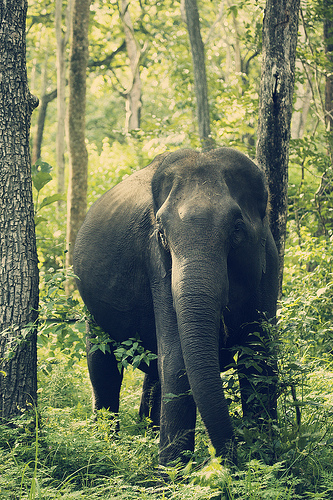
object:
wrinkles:
[177, 260, 216, 295]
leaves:
[46, 300, 56, 318]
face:
[147, 155, 265, 327]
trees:
[0, 0, 333, 423]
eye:
[154, 218, 169, 250]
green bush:
[0, 340, 231, 499]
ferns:
[181, 441, 243, 492]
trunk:
[166, 258, 236, 463]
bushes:
[235, 0, 332, 499]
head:
[150, 146, 269, 471]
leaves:
[41, 258, 56, 288]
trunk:
[1, 0, 40, 425]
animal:
[71, 148, 281, 473]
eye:
[228, 214, 249, 243]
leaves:
[131, 30, 226, 98]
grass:
[0, 223, 333, 500]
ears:
[206, 145, 268, 303]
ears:
[151, 147, 195, 279]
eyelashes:
[151, 224, 165, 233]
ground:
[0, 131, 333, 499]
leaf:
[74, 319, 87, 334]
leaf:
[84, 344, 98, 355]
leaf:
[98, 342, 107, 354]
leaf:
[86, 336, 100, 343]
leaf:
[120, 339, 133, 346]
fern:
[46, 359, 81, 405]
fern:
[230, 458, 303, 497]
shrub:
[224, 306, 333, 499]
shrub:
[276, 260, 332, 395]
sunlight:
[191, 445, 229, 496]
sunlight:
[24, 2, 333, 410]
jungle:
[1, 1, 333, 500]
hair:
[248, 157, 272, 219]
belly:
[72, 159, 157, 348]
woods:
[0, 0, 332, 490]